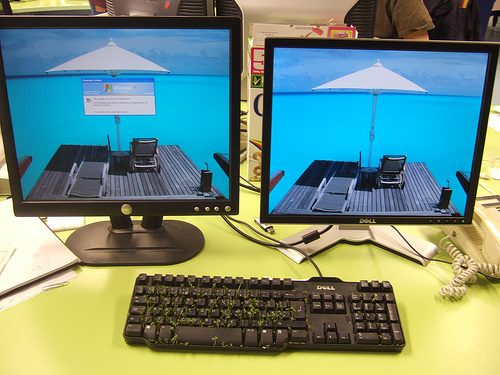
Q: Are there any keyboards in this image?
A: Yes, there is a keyboard.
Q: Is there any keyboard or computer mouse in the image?
A: Yes, there is a keyboard.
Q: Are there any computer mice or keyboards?
A: Yes, there is a keyboard.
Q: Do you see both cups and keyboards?
A: No, there is a keyboard but no cups.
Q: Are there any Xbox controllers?
A: No, there are no Xbox controllers.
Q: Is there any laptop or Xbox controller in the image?
A: No, there are no Xbox controllers or laptops.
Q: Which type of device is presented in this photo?
A: The device is a keyboard.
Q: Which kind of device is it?
A: The device is a keyboard.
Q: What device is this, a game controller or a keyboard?
A: This is a keyboard.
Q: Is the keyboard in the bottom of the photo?
A: Yes, the keyboard is in the bottom of the image.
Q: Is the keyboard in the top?
A: No, the keyboard is in the bottom of the image.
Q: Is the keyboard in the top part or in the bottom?
A: The keyboard is in the bottom of the image.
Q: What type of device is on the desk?
A: The device is a keyboard.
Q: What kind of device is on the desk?
A: The device is a keyboard.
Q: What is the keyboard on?
A: The keyboard is on the desk.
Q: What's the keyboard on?
A: The keyboard is on the desk.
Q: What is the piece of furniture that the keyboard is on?
A: The piece of furniture is a desk.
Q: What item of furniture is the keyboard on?
A: The keyboard is on the desk.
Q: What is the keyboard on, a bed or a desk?
A: The keyboard is on a desk.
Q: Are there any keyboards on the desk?
A: Yes, there is a keyboard on the desk.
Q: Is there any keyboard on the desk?
A: Yes, there is a keyboard on the desk.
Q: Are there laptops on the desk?
A: No, there is a keyboard on the desk.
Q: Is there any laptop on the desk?
A: No, there is a keyboard on the desk.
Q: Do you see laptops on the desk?
A: No, there is a keyboard on the desk.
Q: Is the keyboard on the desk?
A: Yes, the keyboard is on the desk.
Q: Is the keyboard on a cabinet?
A: No, the keyboard is on the desk.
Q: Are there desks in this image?
A: Yes, there is a desk.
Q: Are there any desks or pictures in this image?
A: Yes, there is a desk.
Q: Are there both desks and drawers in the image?
A: No, there is a desk but no drawers.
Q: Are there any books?
A: No, there are no books.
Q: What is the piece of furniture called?
A: The piece of furniture is a desk.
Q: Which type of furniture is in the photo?
A: The furniture is a desk.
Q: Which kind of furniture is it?
A: The piece of furniture is a desk.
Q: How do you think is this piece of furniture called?
A: This is a desk.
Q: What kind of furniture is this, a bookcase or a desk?
A: This is a desk.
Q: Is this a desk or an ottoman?
A: This is a desk.